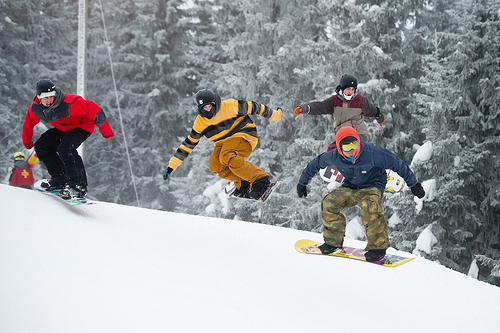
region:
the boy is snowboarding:
[285, 120, 445, 287]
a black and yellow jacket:
[162, 93, 277, 170]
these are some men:
[142, 97, 349, 262]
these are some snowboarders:
[0, 90, 274, 293]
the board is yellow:
[299, 167, 411, 305]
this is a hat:
[183, 83, 218, 126]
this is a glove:
[149, 150, 185, 211]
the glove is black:
[158, 158, 164, 191]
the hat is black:
[163, 98, 227, 117]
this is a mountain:
[95, 218, 191, 330]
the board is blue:
[18, 164, 115, 225]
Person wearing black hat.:
[33, 75, 60, 96]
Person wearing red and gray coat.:
[36, 107, 108, 135]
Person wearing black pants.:
[36, 133, 94, 165]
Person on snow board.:
[47, 170, 101, 216]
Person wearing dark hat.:
[193, 83, 213, 108]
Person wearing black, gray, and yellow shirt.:
[189, 111, 269, 136]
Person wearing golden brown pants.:
[208, 151, 280, 179]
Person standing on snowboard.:
[217, 172, 284, 214]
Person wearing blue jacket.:
[359, 161, 382, 179]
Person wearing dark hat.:
[331, 68, 366, 93]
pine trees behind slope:
[0, 5, 492, 264]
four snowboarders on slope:
[20, 73, 419, 267]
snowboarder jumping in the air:
[165, 89, 282, 201]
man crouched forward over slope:
[23, 78, 114, 190]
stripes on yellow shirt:
[169, 100, 279, 169]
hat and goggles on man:
[336, 128, 360, 160]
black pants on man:
[34, 125, 90, 194]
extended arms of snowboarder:
[160, 96, 280, 178]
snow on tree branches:
[409, 141, 444, 265]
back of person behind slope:
[9, 152, 35, 189]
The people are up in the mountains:
[11, 38, 496, 298]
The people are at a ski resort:
[15, 3, 491, 318]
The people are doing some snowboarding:
[26, 37, 461, 317]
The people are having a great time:
[20, 15, 482, 301]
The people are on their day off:
[18, 55, 448, 306]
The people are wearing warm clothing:
[20, 46, 493, 306]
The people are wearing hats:
[16, 48, 437, 329]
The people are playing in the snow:
[15, 32, 491, 298]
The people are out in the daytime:
[21, 46, 491, 302]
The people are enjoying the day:
[25, 62, 480, 304]